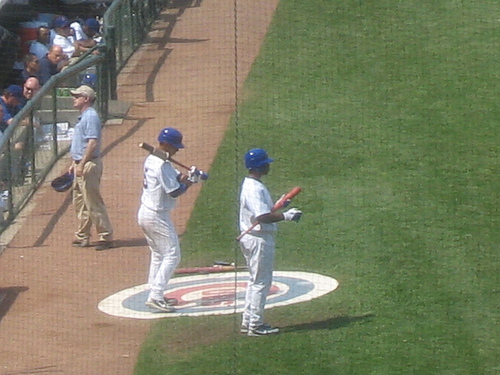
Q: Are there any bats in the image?
A: Yes, there is a bat.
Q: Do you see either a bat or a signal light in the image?
A: Yes, there is a bat.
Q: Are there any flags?
A: No, there are no flags.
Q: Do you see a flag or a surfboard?
A: No, there are no flags or surfboards.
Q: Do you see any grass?
A: Yes, there is grass.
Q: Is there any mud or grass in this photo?
A: Yes, there is grass.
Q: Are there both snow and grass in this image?
A: No, there is grass but no snow.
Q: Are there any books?
A: No, there are no books.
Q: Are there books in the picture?
A: No, there are no books.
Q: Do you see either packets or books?
A: No, there are no books or packets.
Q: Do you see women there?
A: No, there are no women.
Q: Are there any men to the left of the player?
A: Yes, there is a man to the left of the player.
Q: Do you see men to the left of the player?
A: Yes, there is a man to the left of the player.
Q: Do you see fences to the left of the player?
A: No, there is a man to the left of the player.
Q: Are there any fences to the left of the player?
A: No, there is a man to the left of the player.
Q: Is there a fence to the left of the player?
A: No, there is a man to the left of the player.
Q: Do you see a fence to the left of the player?
A: No, there is a man to the left of the player.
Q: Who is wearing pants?
A: The man is wearing pants.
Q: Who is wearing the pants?
A: The man is wearing pants.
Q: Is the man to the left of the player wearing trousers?
A: Yes, the man is wearing trousers.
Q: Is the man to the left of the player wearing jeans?
A: No, the man is wearing trousers.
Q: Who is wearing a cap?
A: The man is wearing a cap.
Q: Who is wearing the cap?
A: The man is wearing a cap.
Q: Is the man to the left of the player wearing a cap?
A: Yes, the man is wearing a cap.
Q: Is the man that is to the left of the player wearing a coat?
A: No, the man is wearing a cap.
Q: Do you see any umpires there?
A: No, there are no umpires.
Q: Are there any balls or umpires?
A: No, there are no umpires or balls.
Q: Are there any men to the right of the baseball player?
A: Yes, there is a man to the right of the player.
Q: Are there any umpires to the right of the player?
A: No, there is a man to the right of the player.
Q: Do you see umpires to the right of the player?
A: No, there is a man to the right of the player.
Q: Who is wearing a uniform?
A: The man is wearing a uniform.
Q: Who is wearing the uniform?
A: The man is wearing a uniform.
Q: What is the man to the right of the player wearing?
A: The man is wearing a uniform.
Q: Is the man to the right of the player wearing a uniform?
A: Yes, the man is wearing a uniform.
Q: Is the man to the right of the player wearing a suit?
A: No, the man is wearing a uniform.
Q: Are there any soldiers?
A: No, there are no soldiers.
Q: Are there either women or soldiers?
A: No, there are no soldiers or women.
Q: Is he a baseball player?
A: Yes, that is a baseball player.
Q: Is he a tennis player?
A: No, that is a baseball player.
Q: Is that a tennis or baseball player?
A: That is a baseball player.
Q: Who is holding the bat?
A: The player is holding the bat.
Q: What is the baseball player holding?
A: The player is holding the bat.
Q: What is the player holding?
A: The player is holding the bat.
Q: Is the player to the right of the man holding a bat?
A: Yes, the player is holding a bat.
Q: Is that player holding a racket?
A: No, the player is holding a bat.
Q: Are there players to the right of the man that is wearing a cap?
A: Yes, there is a player to the right of the man.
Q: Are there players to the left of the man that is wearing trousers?
A: No, the player is to the right of the man.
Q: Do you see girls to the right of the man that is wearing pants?
A: No, there is a player to the right of the man.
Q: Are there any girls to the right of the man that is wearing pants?
A: No, there is a player to the right of the man.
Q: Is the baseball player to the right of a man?
A: Yes, the player is to the right of a man.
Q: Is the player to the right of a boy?
A: No, the player is to the right of a man.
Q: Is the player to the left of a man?
A: No, the player is to the right of a man.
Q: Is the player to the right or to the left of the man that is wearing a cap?
A: The player is to the right of the man.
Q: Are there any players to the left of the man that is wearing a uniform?
A: Yes, there is a player to the left of the man.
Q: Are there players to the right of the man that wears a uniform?
A: No, the player is to the left of the man.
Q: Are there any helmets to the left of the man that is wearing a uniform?
A: No, there is a player to the left of the man.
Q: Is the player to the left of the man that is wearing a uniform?
A: Yes, the player is to the left of the man.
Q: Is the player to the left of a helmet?
A: No, the player is to the left of the man.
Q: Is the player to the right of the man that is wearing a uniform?
A: No, the player is to the left of the man.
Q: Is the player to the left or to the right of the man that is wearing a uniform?
A: The player is to the left of the man.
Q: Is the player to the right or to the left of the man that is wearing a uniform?
A: The player is to the left of the man.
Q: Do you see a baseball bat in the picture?
A: Yes, there is a baseball bat.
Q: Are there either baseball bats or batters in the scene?
A: Yes, there is a baseball bat.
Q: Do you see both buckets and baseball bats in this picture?
A: No, there is a baseball bat but no buckets.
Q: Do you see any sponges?
A: No, there are no sponges.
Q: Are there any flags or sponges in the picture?
A: No, there are no sponges or flags.